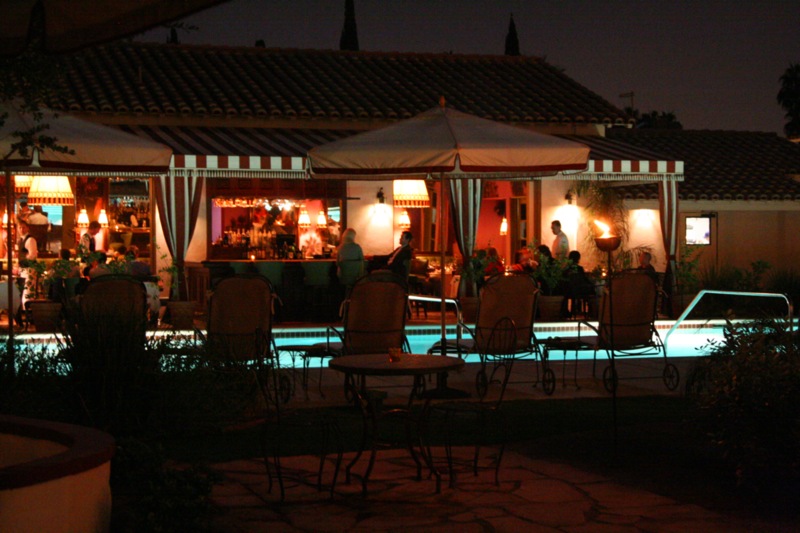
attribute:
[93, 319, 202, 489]
building — dark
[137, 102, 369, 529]
wall — dark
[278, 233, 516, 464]
pool — blue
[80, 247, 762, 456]
chairs — lined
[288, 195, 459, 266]
man — standing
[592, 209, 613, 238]
fire — blazing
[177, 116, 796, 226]
awning — striped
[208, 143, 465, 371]
people — seated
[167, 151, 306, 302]
bar — stocked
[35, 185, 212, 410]
waiter — worked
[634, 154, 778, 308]
window — open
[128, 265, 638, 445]
chairs — lined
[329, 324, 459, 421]
table — brown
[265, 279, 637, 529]
pool — blue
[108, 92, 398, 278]
canopy — striped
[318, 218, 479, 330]
person — seated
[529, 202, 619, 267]
man — standing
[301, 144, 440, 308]
people — seated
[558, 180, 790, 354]
railing — metal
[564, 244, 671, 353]
chair — empty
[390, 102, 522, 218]
umbrella — white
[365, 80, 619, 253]
umbrella — tan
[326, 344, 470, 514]
table — brown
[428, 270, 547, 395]
chair — brown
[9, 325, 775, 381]
swimming pool — blue